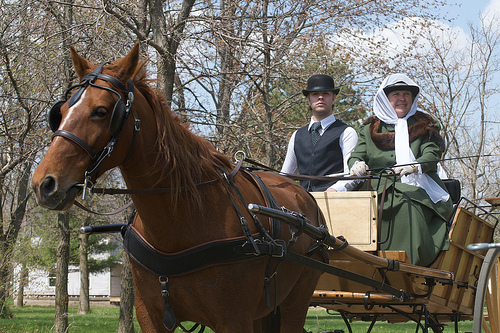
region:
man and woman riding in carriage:
[243, 58, 443, 231]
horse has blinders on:
[35, 93, 132, 133]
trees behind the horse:
[56, 7, 268, 60]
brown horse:
[16, 37, 320, 319]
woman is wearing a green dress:
[356, 114, 454, 279]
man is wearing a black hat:
[290, 58, 332, 109]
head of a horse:
[18, 47, 185, 222]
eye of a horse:
[87, 105, 115, 122]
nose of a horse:
[27, 169, 65, 186]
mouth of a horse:
[30, 186, 107, 216]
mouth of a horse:
[33, 183, 84, 210]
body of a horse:
[119, 120, 330, 303]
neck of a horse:
[113, 96, 214, 211]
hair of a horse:
[162, 118, 209, 154]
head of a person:
[299, 65, 341, 113]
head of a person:
[367, 66, 416, 118]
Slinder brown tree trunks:
[43, 218, 75, 312]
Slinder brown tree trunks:
[78, 226, 89, 311]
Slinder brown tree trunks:
[104, 246, 131, 328]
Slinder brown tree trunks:
[15, 248, 34, 313]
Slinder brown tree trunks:
[1, 219, 31, 319]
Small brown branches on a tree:
[470, 21, 490, 72]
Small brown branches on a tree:
[425, 61, 463, 106]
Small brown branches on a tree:
[465, 118, 496, 182]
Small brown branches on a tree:
[444, 118, 470, 175]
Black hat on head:
[295, 70, 341, 96]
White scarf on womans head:
[372, 58, 422, 162]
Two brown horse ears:
[67, 37, 147, 79]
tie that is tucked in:
[308, 118, 324, 147]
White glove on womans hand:
[349, 157, 369, 177]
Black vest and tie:
[290, 121, 346, 177]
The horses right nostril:
[35, 167, 60, 197]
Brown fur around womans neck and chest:
[362, 115, 442, 150]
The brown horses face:
[25, 35, 145, 200]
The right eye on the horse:
[85, 95, 110, 125]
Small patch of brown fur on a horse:
[185, 288, 216, 313]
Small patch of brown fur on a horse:
[217, 283, 250, 314]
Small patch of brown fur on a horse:
[121, 280, 159, 318]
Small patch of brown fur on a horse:
[274, 266, 296, 289]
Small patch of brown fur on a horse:
[279, 301, 294, 326]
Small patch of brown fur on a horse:
[270, 173, 302, 205]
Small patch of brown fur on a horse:
[185, 183, 230, 232]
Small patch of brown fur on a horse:
[138, 137, 175, 184]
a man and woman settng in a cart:
[265, 70, 466, 290]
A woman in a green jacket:
[348, 88, 463, 237]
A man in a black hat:
[294, 45, 337, 187]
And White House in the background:
[3, 233, 125, 305]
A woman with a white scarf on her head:
[368, 65, 433, 177]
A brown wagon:
[321, 221, 486, 317]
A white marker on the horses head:
[53, 79, 86, 143]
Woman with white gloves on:
[343, 148, 420, 200]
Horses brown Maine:
[113, 97, 202, 187]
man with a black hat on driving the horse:
[268, 50, 375, 216]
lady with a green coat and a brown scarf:
[348, 57, 450, 258]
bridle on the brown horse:
[75, 204, 297, 297]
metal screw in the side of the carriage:
[452, 220, 497, 269]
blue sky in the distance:
[440, 6, 492, 70]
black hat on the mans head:
[288, 65, 360, 100]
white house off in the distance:
[7, 215, 125, 316]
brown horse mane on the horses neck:
[134, 81, 239, 204]